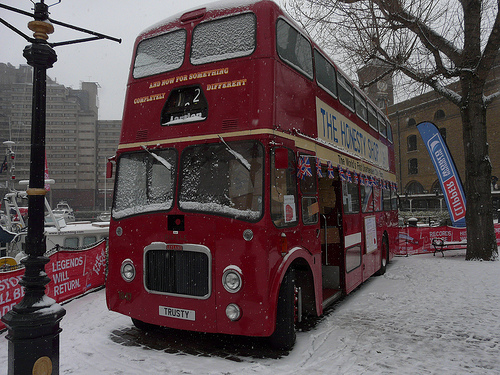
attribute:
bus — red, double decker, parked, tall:
[107, 1, 401, 351]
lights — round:
[115, 226, 253, 320]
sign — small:
[157, 306, 196, 320]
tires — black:
[130, 231, 389, 350]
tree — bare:
[281, 1, 499, 260]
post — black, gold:
[2, 3, 122, 373]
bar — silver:
[320, 212, 329, 266]